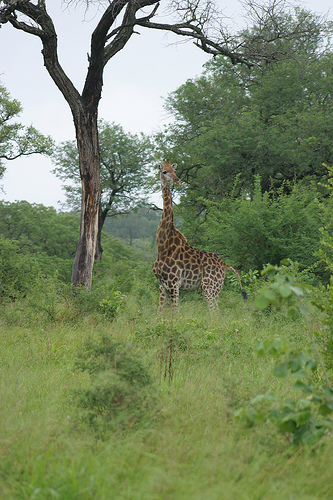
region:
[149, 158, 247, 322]
giraffe in a field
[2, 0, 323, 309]
a withered leafless tree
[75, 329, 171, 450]
small dark green shrub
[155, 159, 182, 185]
head of a giraffe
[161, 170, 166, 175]
eye of a giraffe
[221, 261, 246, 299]
a giraffe's tail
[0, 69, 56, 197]
branches of a tree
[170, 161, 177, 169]
ear of a giraffe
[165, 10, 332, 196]
a tree in the distacne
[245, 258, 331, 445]
a small shrub with leaves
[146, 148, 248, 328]
giraffe standing in grass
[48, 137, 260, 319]
giraffe standing near tree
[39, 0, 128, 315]
tall tree in Africa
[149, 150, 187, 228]
giraffe head looking left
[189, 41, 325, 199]
large trees in background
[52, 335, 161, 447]
small foliage in foreground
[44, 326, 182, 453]
out-of-focus foliage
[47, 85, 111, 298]
tree trunk with striated bark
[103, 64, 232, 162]
trees and sky in background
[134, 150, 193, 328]
giraffe and its weird neck muscles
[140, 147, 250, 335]
giraffe in the grass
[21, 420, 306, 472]
green grasses by a giraffe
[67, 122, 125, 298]
trunk of a tree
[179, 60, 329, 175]
green leaves on a tree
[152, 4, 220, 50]
bare branches of a tree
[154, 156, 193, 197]
head of a giraffe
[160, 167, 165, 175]
right eye of a giraffe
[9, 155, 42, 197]
hazy blye sky in the distance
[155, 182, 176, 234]
neck on a giraffe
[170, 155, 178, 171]
left ear of a giraffe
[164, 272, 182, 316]
leg of a giraffe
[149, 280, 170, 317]
leg of a giraffe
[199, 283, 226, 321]
leg of a giraffe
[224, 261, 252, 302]
tail of a giraffe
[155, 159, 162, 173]
ear of a giraffe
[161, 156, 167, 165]
horn of a giraffe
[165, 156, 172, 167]
horn of a giraffe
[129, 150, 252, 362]
a giraffe in a field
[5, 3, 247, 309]
a giraffe on side a tree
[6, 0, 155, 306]
a tree without trees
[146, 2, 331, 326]
a giraffe in front a tree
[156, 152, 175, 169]
horns on top a head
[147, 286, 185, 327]
front feet of giraffe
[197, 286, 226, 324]
back feet of giraffe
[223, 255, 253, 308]
tail of giraffe with turf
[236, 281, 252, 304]
a black turf of giraffe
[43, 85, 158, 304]
a small tree behind a trunk